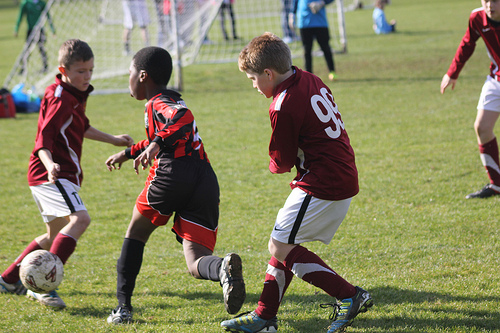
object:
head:
[127, 45, 174, 101]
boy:
[104, 45, 247, 325]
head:
[57, 37, 97, 92]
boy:
[0, 37, 135, 311]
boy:
[220, 31, 375, 332]